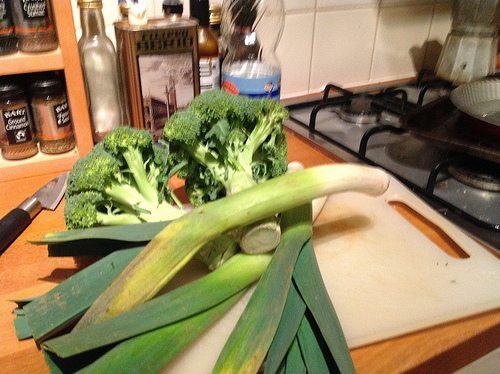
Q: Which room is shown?
A: It is a kitchen.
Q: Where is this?
A: This is at the kitchen.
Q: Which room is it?
A: It is a kitchen.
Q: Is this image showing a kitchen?
A: Yes, it is showing a kitchen.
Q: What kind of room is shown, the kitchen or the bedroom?
A: It is the kitchen.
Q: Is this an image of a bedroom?
A: No, the picture is showing a kitchen.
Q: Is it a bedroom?
A: No, it is a kitchen.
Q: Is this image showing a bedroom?
A: No, the picture is showing a kitchen.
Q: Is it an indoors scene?
A: Yes, it is indoors.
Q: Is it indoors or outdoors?
A: It is indoors.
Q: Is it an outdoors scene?
A: No, it is indoors.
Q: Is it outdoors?
A: No, it is indoors.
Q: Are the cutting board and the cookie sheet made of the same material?
A: No, the cutting board is made of plastic and the cookie sheet is made of metal.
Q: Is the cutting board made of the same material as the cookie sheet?
A: No, the cutting board is made of plastic and the cookie sheet is made of metal.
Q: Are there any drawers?
A: No, there are no drawers.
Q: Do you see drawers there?
A: No, there are no drawers.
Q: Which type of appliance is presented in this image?
A: The appliance is a stove.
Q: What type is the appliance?
A: The appliance is a stove.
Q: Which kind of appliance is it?
A: The appliance is a stove.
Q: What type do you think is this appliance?
A: This is a stove.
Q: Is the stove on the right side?
A: Yes, the stove is on the right of the image.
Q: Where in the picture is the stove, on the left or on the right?
A: The stove is on the right of the image.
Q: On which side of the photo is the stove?
A: The stove is on the right of the image.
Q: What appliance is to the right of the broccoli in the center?
A: The appliance is a stove.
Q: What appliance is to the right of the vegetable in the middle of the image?
A: The appliance is a stove.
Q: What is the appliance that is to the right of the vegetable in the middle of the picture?
A: The appliance is a stove.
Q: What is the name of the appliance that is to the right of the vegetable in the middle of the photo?
A: The appliance is a stove.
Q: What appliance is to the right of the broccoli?
A: The appliance is a stove.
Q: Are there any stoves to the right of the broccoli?
A: Yes, there is a stove to the right of the broccoli.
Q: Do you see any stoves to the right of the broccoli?
A: Yes, there is a stove to the right of the broccoli.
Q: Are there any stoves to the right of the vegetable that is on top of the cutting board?
A: Yes, there is a stove to the right of the broccoli.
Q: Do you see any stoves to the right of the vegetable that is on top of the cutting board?
A: Yes, there is a stove to the right of the broccoli.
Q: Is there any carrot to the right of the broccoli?
A: No, there is a stove to the right of the broccoli.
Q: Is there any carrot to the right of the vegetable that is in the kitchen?
A: No, there is a stove to the right of the broccoli.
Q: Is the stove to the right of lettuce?
A: No, the stove is to the right of the broccoli.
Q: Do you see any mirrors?
A: No, there are no mirrors.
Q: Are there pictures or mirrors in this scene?
A: No, there are no mirrors or pictures.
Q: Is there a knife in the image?
A: Yes, there is a knife.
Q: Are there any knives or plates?
A: Yes, there is a knife.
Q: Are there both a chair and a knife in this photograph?
A: No, there is a knife but no chairs.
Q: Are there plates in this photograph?
A: No, there are no plates.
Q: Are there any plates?
A: No, there are no plates.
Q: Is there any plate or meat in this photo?
A: No, there are no plates or meat.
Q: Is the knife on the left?
A: Yes, the knife is on the left of the image.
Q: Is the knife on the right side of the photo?
A: No, the knife is on the left of the image.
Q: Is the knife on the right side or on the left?
A: The knife is on the left of the image.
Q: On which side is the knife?
A: The knife is on the left of the image.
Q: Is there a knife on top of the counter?
A: Yes, there is a knife on top of the counter.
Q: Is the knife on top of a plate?
A: No, the knife is on top of the counter.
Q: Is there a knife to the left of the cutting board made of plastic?
A: Yes, there is a knife to the left of the cutting board.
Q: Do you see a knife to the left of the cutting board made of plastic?
A: Yes, there is a knife to the left of the cutting board.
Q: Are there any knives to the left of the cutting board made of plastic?
A: Yes, there is a knife to the left of the cutting board.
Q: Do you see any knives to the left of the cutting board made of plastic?
A: Yes, there is a knife to the left of the cutting board.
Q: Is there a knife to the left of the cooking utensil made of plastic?
A: Yes, there is a knife to the left of the cutting board.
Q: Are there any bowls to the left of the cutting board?
A: No, there is a knife to the left of the cutting board.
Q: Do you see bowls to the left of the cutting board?
A: No, there is a knife to the left of the cutting board.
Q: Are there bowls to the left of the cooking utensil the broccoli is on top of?
A: No, there is a knife to the left of the cutting board.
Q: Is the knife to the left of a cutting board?
A: Yes, the knife is to the left of a cutting board.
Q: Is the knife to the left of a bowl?
A: No, the knife is to the left of a cutting board.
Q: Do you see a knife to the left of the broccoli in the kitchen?
A: Yes, there is a knife to the left of the broccoli.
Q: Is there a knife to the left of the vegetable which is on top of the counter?
A: Yes, there is a knife to the left of the broccoli.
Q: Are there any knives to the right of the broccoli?
A: No, the knife is to the left of the broccoli.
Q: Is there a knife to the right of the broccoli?
A: No, the knife is to the left of the broccoli.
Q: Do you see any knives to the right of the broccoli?
A: No, the knife is to the left of the broccoli.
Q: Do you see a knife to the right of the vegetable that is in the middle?
A: No, the knife is to the left of the broccoli.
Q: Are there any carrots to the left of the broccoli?
A: No, there is a knife to the left of the broccoli.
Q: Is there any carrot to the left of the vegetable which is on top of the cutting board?
A: No, there is a knife to the left of the broccoli.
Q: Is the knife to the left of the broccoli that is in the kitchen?
A: Yes, the knife is to the left of the broccoli.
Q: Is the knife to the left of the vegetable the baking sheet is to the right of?
A: Yes, the knife is to the left of the broccoli.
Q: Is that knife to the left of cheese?
A: No, the knife is to the left of the broccoli.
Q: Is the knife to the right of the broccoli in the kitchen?
A: No, the knife is to the left of the broccoli.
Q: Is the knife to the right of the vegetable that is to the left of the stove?
A: No, the knife is to the left of the broccoli.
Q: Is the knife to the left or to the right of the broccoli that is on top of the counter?
A: The knife is to the left of the broccoli.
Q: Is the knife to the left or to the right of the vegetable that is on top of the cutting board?
A: The knife is to the left of the broccoli.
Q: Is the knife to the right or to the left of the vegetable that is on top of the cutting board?
A: The knife is to the left of the broccoli.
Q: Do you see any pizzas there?
A: No, there are no pizzas.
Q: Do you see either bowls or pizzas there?
A: No, there are no pizzas or bowls.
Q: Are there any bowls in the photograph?
A: No, there are no bowls.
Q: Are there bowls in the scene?
A: No, there are no bowls.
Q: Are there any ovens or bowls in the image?
A: No, there are no bowls or ovens.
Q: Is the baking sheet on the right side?
A: Yes, the baking sheet is on the right of the image.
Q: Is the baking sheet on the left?
A: No, the baking sheet is on the right of the image.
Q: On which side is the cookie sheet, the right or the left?
A: The cookie sheet is on the right of the image.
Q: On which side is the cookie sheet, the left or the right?
A: The cookie sheet is on the right of the image.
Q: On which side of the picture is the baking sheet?
A: The baking sheet is on the right of the image.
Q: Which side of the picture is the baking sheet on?
A: The baking sheet is on the right of the image.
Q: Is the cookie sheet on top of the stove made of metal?
A: Yes, the cookie sheet is made of metal.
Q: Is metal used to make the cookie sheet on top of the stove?
A: Yes, the cookie sheet is made of metal.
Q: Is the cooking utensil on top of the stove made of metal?
A: Yes, the cookie sheet is made of metal.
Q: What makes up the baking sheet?
A: The baking sheet is made of metal.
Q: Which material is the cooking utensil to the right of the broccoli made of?
A: The baking sheet is made of metal.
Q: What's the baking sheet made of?
A: The baking sheet is made of metal.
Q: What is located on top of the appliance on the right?
A: The baking sheet is on top of the stove.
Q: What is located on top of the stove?
A: The baking sheet is on top of the stove.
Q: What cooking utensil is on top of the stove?
A: The cooking utensil is a baking sheet.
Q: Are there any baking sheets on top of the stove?
A: Yes, there is a baking sheet on top of the stove.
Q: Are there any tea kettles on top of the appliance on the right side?
A: No, there is a baking sheet on top of the stove.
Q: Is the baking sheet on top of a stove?
A: Yes, the baking sheet is on top of a stove.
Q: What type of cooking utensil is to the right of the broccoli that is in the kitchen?
A: The cooking utensil is a baking sheet.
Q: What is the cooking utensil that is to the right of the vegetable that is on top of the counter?
A: The cooking utensil is a baking sheet.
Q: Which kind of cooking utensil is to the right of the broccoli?
A: The cooking utensil is a baking sheet.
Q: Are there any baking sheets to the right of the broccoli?
A: Yes, there is a baking sheet to the right of the broccoli.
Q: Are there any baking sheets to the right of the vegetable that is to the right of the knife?
A: Yes, there is a baking sheet to the right of the broccoli.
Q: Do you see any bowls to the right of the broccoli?
A: No, there is a baking sheet to the right of the broccoli.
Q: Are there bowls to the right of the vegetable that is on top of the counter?
A: No, there is a baking sheet to the right of the broccoli.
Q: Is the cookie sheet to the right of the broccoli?
A: Yes, the cookie sheet is to the right of the broccoli.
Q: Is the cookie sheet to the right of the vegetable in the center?
A: Yes, the cookie sheet is to the right of the broccoli.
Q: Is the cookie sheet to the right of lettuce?
A: No, the cookie sheet is to the right of the broccoli.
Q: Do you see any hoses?
A: No, there are no hoses.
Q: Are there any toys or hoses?
A: No, there are no hoses or toys.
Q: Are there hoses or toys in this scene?
A: No, there are no hoses or toys.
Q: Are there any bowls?
A: No, there are no bowls.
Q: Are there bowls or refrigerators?
A: No, there are no bowls or refrigerators.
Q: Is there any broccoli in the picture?
A: Yes, there is broccoli.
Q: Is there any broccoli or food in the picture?
A: Yes, there is broccoli.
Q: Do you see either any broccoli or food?
A: Yes, there is broccoli.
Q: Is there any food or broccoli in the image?
A: Yes, there is broccoli.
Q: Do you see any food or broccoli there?
A: Yes, there is broccoli.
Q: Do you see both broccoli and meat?
A: No, there is broccoli but no meat.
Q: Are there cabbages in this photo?
A: No, there are no cabbages.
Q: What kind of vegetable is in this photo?
A: The vegetable is broccoli.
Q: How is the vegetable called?
A: The vegetable is broccoli.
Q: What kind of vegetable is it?
A: The vegetable is broccoli.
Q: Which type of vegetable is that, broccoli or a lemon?
A: This is broccoli.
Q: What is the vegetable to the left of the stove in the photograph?
A: The vegetable is broccoli.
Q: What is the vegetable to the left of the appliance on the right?
A: The vegetable is broccoli.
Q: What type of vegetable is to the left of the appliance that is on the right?
A: The vegetable is broccoli.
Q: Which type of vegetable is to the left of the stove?
A: The vegetable is broccoli.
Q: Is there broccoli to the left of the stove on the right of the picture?
A: Yes, there is broccoli to the left of the stove.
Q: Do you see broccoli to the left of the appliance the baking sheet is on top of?
A: Yes, there is broccoli to the left of the stove.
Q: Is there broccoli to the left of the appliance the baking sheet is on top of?
A: Yes, there is broccoli to the left of the stove.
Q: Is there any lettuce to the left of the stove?
A: No, there is broccoli to the left of the stove.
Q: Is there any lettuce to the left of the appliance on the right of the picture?
A: No, there is broccoli to the left of the stove.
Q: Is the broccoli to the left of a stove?
A: Yes, the broccoli is to the left of a stove.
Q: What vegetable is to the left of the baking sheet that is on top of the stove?
A: The vegetable is broccoli.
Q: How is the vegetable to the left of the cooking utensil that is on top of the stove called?
A: The vegetable is broccoli.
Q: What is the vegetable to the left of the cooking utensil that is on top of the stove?
A: The vegetable is broccoli.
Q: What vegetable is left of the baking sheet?
A: The vegetable is broccoli.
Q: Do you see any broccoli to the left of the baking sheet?
A: Yes, there is broccoli to the left of the baking sheet.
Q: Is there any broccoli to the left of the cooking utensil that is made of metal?
A: Yes, there is broccoli to the left of the baking sheet.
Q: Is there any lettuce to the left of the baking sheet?
A: No, there is broccoli to the left of the baking sheet.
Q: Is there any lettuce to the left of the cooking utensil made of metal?
A: No, there is broccoli to the left of the baking sheet.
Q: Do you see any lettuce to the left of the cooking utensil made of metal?
A: No, there is broccoli to the left of the baking sheet.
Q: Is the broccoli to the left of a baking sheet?
A: Yes, the broccoli is to the left of a baking sheet.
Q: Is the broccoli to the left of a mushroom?
A: No, the broccoli is to the left of a baking sheet.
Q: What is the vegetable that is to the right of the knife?
A: The vegetable is broccoli.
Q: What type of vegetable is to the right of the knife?
A: The vegetable is broccoli.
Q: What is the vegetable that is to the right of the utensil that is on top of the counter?
A: The vegetable is broccoli.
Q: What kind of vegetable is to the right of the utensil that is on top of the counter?
A: The vegetable is broccoli.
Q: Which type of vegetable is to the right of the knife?
A: The vegetable is broccoli.